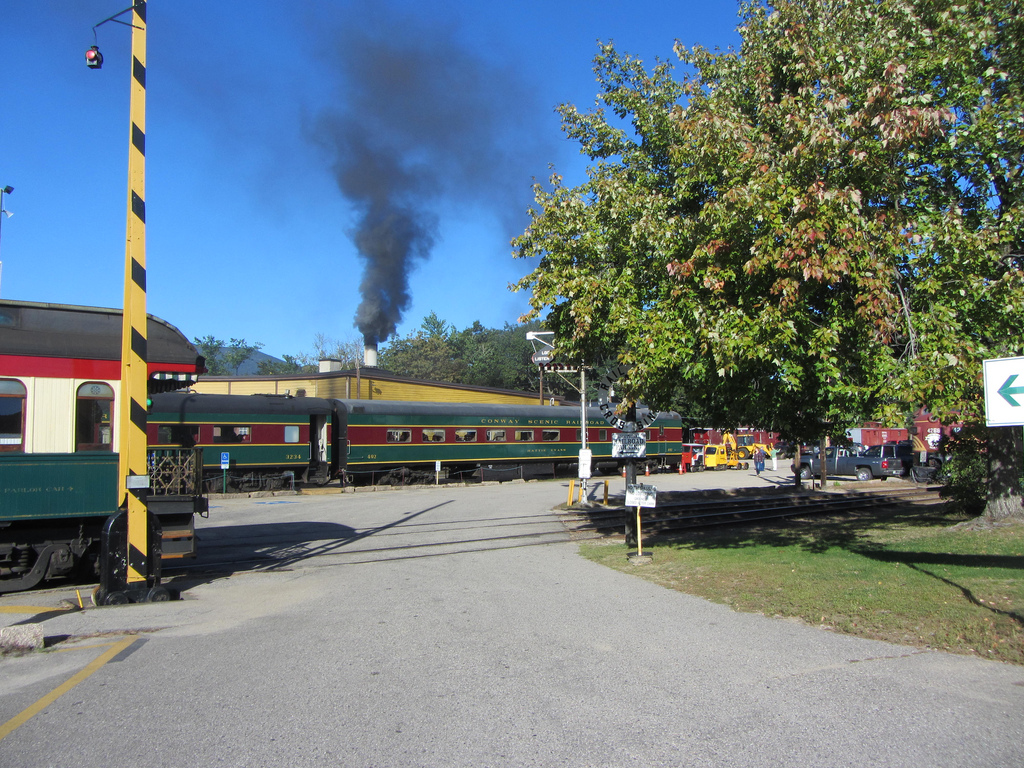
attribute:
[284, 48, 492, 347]
smoke — black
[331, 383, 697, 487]
train car — green, red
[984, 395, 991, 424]
sign — white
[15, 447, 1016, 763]
road — cement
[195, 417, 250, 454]
window — rectangular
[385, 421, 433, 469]
window — rectangular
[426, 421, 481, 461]
window — rectangular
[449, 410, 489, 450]
window — rectangular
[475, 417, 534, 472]
window — rectangular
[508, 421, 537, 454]
window — rectangular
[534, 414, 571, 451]
window — rectangular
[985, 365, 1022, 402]
arrow — green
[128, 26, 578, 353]
smoke — dark gray